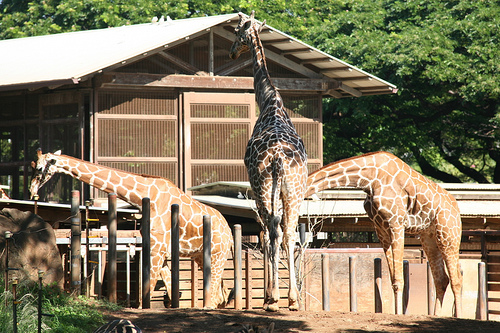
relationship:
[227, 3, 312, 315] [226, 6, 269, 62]
giraffe has head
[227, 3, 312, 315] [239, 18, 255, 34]
giraffe has ear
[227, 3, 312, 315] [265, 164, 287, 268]
giraffe has tail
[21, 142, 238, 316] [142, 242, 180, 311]
giraffe has front legs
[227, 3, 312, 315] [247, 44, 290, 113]
giraffe has neck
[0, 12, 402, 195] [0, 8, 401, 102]
building has roof